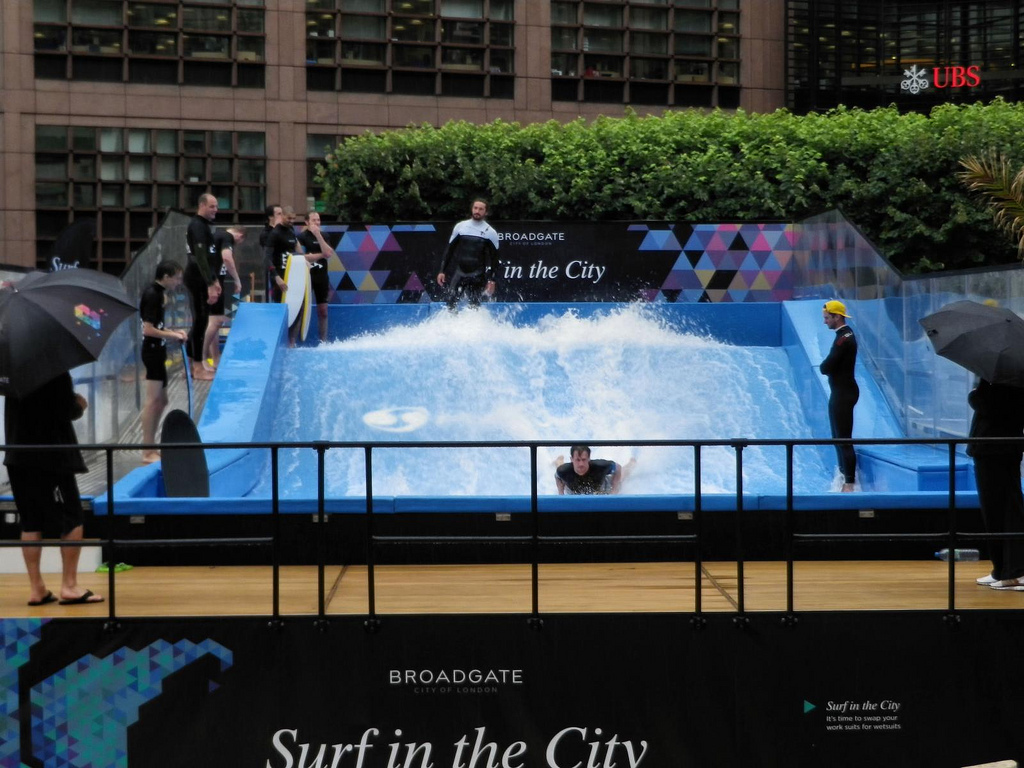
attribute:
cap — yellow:
[816, 298, 856, 321]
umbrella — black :
[0, 260, 146, 385]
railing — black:
[2, 433, 1023, 617]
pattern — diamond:
[631, 212, 898, 302]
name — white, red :
[895, 58, 985, 94]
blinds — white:
[94, 131, 192, 207]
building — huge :
[3, 1, 1021, 277]